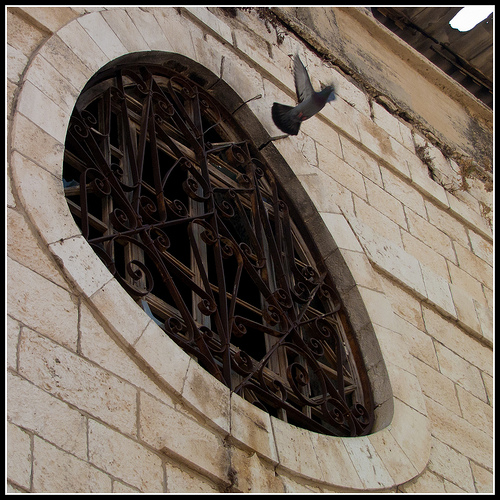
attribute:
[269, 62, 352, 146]
pigeon — flying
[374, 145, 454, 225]
house wall — white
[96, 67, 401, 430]
window — metal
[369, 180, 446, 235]
wall — white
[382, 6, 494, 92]
tiles — roof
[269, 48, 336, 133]
pigeon — flying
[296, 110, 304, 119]
leg — retracted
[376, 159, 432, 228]
brick — white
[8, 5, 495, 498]
wall — white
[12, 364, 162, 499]
brick house — white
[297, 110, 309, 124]
legs — Red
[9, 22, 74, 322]
house wall — white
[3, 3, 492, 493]
house — white